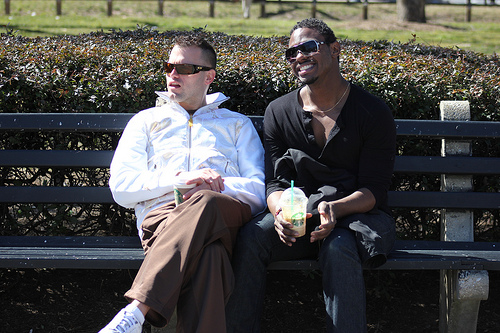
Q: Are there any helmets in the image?
A: No, there are no helmets.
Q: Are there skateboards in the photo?
A: No, there are no skateboards.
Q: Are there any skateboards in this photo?
A: No, there are no skateboards.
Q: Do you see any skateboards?
A: No, there are no skateboards.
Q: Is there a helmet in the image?
A: No, there are no helmets.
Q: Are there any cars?
A: No, there are no cars.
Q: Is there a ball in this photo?
A: No, there are no balls.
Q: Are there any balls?
A: No, there are no balls.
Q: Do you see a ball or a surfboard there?
A: No, there are no balls or surfboards.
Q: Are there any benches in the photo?
A: Yes, there is a bench.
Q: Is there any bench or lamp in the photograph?
A: Yes, there is a bench.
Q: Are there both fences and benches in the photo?
A: Yes, there are both a bench and a fence.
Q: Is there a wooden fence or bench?
A: Yes, there is a wood bench.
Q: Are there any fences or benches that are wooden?
A: Yes, the bench is wooden.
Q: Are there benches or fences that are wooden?
A: Yes, the bench is wooden.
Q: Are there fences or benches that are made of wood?
A: Yes, the bench is made of wood.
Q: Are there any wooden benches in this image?
A: Yes, there is a wood bench.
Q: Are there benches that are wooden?
A: Yes, there is a bench that is wooden.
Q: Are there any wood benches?
A: Yes, there is a bench that is made of wood.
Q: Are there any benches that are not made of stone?
A: Yes, there is a bench that is made of wood.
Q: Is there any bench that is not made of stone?
A: Yes, there is a bench that is made of wood.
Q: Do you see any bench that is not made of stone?
A: Yes, there is a bench that is made of wood.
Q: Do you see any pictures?
A: No, there are no pictures.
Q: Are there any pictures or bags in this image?
A: No, there are no pictures or bags.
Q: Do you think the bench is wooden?
A: Yes, the bench is wooden.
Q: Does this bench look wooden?
A: Yes, the bench is wooden.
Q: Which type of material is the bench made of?
A: The bench is made of wood.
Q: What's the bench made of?
A: The bench is made of wood.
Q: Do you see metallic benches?
A: No, there is a bench but it is wooden.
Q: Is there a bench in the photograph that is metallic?
A: No, there is a bench but it is wooden.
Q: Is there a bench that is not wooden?
A: No, there is a bench but it is wooden.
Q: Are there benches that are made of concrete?
A: No, there is a bench but it is made of wood.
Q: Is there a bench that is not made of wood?
A: No, there is a bench but it is made of wood.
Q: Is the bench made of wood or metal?
A: The bench is made of wood.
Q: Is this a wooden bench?
A: Yes, this is a wooden bench.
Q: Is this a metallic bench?
A: No, this is a wooden bench.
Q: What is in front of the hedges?
A: The bench is in front of the hedges.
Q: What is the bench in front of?
A: The bench is in front of the hedges.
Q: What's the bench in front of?
A: The bench is in front of the hedges.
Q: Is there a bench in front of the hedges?
A: Yes, there is a bench in front of the hedges.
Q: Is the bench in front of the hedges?
A: Yes, the bench is in front of the hedges.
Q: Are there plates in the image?
A: No, there are no plates.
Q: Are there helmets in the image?
A: No, there are no helmets.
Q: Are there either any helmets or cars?
A: No, there are no helmets or cars.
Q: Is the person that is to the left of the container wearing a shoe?
A: Yes, the person is wearing a shoe.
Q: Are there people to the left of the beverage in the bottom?
A: Yes, there is a person to the left of the beverage.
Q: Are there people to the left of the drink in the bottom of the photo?
A: Yes, there is a person to the left of the beverage.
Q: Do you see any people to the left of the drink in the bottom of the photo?
A: Yes, there is a person to the left of the beverage.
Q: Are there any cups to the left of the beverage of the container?
A: No, there is a person to the left of the beverage.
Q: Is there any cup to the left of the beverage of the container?
A: No, there is a person to the left of the beverage.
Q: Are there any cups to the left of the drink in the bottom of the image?
A: No, there is a person to the left of the beverage.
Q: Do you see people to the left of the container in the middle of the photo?
A: Yes, there is a person to the left of the container.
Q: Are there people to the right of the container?
A: No, the person is to the left of the container.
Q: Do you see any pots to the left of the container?
A: No, there is a person to the left of the container.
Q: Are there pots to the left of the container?
A: No, there is a person to the left of the container.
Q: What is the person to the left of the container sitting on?
A: The person is sitting on the bench.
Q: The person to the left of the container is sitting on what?
A: The person is sitting on the bench.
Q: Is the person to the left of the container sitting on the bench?
A: Yes, the person is sitting on the bench.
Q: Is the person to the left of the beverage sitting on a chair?
A: No, the person is sitting on the bench.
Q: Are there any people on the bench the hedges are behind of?
A: Yes, there is a person on the bench.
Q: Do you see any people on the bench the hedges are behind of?
A: Yes, there is a person on the bench.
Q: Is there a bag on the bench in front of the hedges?
A: No, there is a person on the bench.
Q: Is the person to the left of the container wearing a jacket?
A: Yes, the person is wearing a jacket.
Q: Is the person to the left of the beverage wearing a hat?
A: No, the person is wearing a jacket.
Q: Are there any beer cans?
A: No, there are no beer cans.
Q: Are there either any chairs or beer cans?
A: No, there are no beer cans or chairs.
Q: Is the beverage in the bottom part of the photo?
A: Yes, the beverage is in the bottom of the image.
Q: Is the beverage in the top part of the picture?
A: No, the beverage is in the bottom of the image.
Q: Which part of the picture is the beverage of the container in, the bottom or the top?
A: The beverage is in the bottom of the image.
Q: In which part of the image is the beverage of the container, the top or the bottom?
A: The beverage is in the bottom of the image.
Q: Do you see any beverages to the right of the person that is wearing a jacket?
A: Yes, there is a beverage to the right of the person.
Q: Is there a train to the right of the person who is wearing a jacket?
A: No, there is a beverage to the right of the person.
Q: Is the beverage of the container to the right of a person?
A: Yes, the beverage is to the right of a person.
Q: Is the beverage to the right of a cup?
A: No, the beverage is to the right of a person.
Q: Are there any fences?
A: Yes, there is a fence.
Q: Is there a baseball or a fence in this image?
A: Yes, there is a fence.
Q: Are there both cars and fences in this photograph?
A: No, there is a fence but no cars.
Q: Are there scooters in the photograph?
A: No, there are no scooters.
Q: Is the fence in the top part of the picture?
A: Yes, the fence is in the top of the image.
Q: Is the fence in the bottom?
A: No, the fence is in the top of the image.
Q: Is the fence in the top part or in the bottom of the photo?
A: The fence is in the top of the image.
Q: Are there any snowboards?
A: No, there are no snowboards.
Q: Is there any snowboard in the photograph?
A: No, there are no snowboards.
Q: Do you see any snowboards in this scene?
A: No, there are no snowboards.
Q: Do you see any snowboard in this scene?
A: No, there are no snowboards.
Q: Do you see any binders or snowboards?
A: No, there are no snowboards or binders.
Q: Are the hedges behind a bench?
A: Yes, the hedges are behind a bench.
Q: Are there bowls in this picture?
A: No, there are no bowls.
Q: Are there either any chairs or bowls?
A: No, there are no bowls or chairs.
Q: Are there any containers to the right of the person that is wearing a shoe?
A: Yes, there is a container to the right of the person.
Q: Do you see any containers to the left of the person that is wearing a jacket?
A: No, the container is to the right of the person.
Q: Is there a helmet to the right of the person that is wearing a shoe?
A: No, there is a container to the right of the person.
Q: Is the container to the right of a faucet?
A: No, the container is to the right of the person.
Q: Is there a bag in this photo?
A: No, there are no bags.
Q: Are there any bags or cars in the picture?
A: No, there are no bags or cars.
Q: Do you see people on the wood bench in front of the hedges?
A: Yes, there are people on the bench.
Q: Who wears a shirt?
A: The people wear a shirt.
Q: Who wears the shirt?
A: The people wear a shirt.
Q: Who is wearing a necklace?
A: The people are wearing a necklace.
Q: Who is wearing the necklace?
A: The people are wearing a necklace.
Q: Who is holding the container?
A: The people are holding the container.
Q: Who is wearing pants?
A: The people are wearing pants.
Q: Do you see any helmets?
A: No, there are no helmets.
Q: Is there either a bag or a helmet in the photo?
A: No, there are no helmets or bags.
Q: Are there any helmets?
A: No, there are no helmets.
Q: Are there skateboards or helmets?
A: No, there are no helmets or skateboards.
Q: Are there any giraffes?
A: No, there are no giraffes.